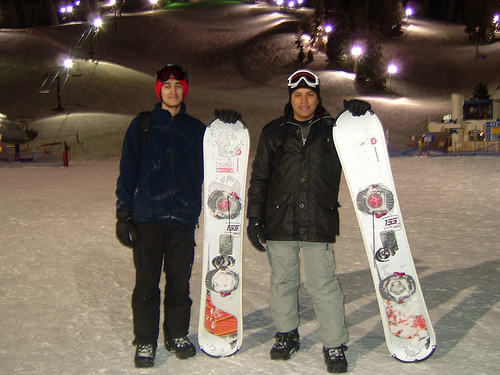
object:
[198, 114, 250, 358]
snowboard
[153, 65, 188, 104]
hat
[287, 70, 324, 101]
hat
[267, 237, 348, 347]
pants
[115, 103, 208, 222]
jacket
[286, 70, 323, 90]
goggles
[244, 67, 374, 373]
man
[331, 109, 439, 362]
snowboard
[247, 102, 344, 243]
coat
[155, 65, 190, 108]
head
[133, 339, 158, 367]
boots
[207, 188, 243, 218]
decals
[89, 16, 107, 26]
lights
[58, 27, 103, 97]
slope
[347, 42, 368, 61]
light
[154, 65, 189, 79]
eye gear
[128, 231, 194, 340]
pant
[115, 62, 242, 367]
man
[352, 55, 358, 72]
pole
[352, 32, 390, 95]
tree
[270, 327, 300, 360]
shoe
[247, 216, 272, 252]
gloves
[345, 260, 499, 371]
shadow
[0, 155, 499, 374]
ground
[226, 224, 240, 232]
155